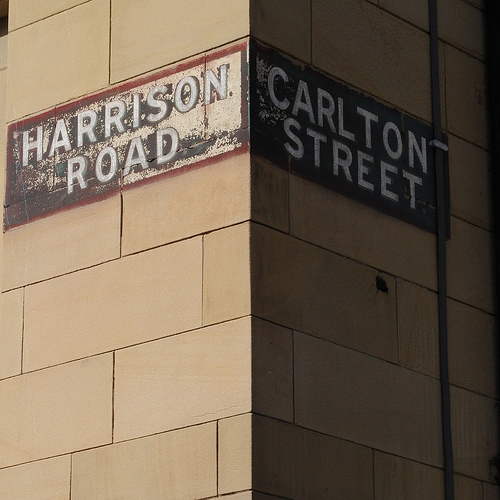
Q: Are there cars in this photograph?
A: No, there are no cars.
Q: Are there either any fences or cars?
A: No, there are no cars or fences.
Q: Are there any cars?
A: No, there are no cars.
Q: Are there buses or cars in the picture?
A: No, there are no cars or buses.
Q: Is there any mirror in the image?
A: No, there are no mirrors.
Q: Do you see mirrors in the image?
A: No, there are no mirrors.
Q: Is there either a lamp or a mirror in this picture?
A: No, there are no mirrors or lamps.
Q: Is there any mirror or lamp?
A: No, there are no mirrors or lamps.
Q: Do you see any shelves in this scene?
A: No, there are no shelves.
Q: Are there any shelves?
A: No, there are no shelves.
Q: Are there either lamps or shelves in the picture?
A: No, there are no shelves or lamps.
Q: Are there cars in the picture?
A: No, there are no cars.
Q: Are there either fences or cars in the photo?
A: No, there are no cars or fences.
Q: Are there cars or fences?
A: No, there are no cars or fences.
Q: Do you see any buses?
A: No, there are no buses.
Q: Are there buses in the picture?
A: No, there are no buses.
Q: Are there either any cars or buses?
A: No, there are no buses or cars.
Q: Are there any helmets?
A: No, there are no helmets.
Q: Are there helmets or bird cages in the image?
A: No, there are no helmets or bird cages.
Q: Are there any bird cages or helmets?
A: No, there are no helmets or bird cages.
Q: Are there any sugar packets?
A: No, there are no sugar packets.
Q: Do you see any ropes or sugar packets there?
A: No, there are no sugar packets or ropes.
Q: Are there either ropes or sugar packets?
A: No, there are no sugar packets or ropes.